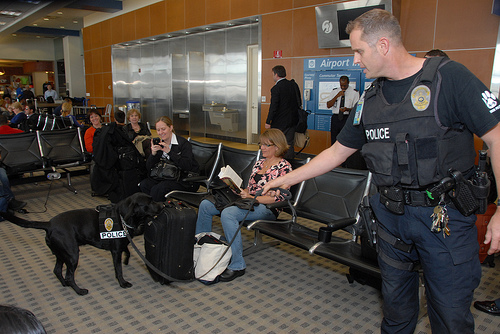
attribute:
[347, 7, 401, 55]
hair — graying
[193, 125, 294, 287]
woman — reading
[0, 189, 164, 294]
police dog — black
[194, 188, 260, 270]
jeans — blue 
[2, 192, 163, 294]
dog — working, black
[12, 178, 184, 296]
dog — sniffing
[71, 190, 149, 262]
police dog — sniffing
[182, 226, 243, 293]
bag — white, canvas